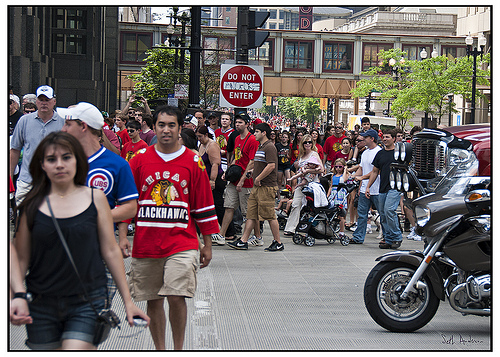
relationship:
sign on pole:
[219, 64, 265, 112] [233, 10, 251, 114]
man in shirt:
[127, 102, 219, 286] [123, 146, 217, 256]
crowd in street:
[12, 89, 419, 246] [186, 247, 493, 350]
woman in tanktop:
[9, 131, 150, 356] [17, 186, 110, 290]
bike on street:
[363, 159, 491, 336] [186, 247, 493, 350]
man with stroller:
[355, 131, 383, 247] [293, 174, 362, 249]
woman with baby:
[290, 134, 325, 188] [287, 160, 322, 183]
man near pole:
[208, 113, 265, 247] [233, 10, 251, 114]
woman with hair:
[9, 131, 150, 356] [14, 132, 88, 234]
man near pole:
[226, 125, 285, 250] [233, 10, 251, 114]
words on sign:
[226, 72, 259, 103] [219, 64, 265, 112]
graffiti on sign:
[224, 82, 260, 93] [219, 64, 265, 112]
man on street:
[127, 102, 219, 286] [186, 247, 493, 350]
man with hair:
[127, 102, 219, 286] [151, 105, 184, 120]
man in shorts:
[127, 102, 219, 286] [126, 248, 201, 303]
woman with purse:
[9, 131, 150, 356] [94, 310, 121, 345]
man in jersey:
[59, 103, 139, 226] [73, 149, 137, 229]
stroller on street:
[293, 174, 362, 249] [186, 247, 493, 350]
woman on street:
[9, 131, 150, 356] [186, 247, 493, 350]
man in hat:
[59, 103, 139, 226] [59, 101, 104, 130]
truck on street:
[388, 121, 499, 208] [186, 247, 493, 350]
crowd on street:
[12, 89, 419, 246] [186, 247, 493, 350]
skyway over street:
[117, 20, 483, 80] [186, 247, 493, 350]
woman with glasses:
[290, 134, 325, 188] [304, 140, 312, 145]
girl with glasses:
[329, 156, 349, 229] [335, 165, 345, 169]